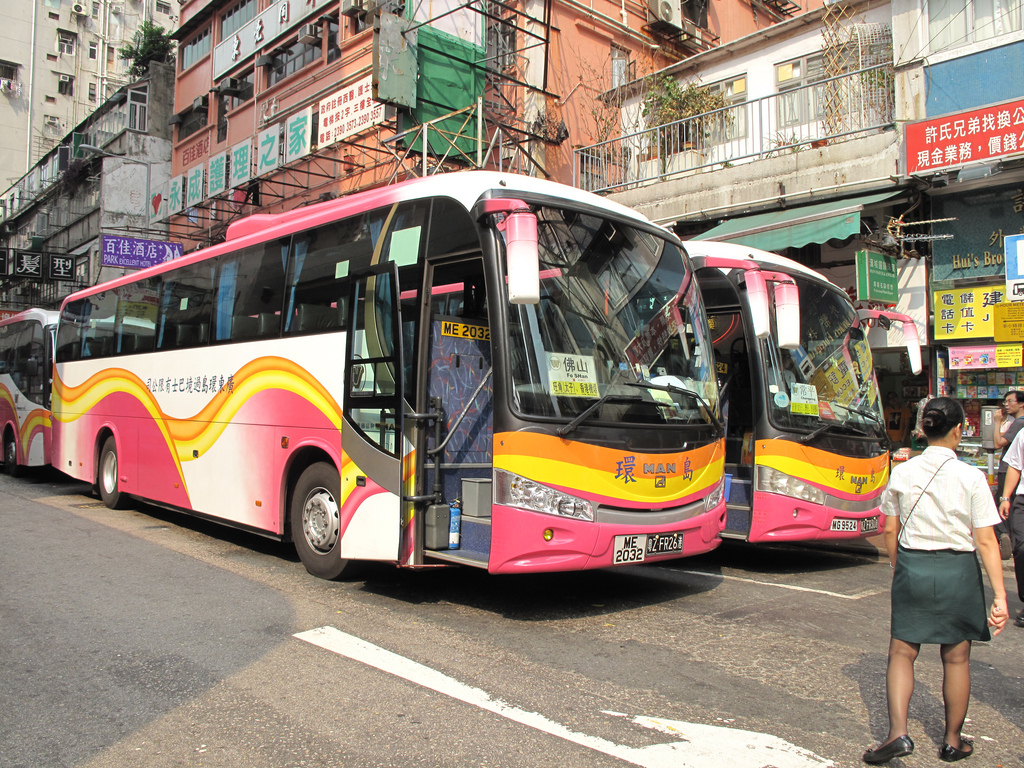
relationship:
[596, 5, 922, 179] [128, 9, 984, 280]
wall on side of building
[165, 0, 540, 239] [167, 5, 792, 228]
wall on building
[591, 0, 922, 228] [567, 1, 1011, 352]
wall on building